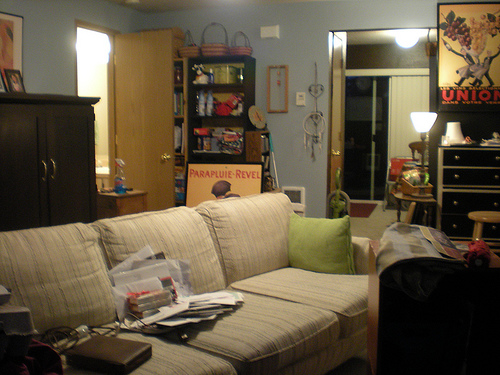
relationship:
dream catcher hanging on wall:
[299, 58, 325, 168] [131, 1, 441, 213]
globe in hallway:
[393, 37, 418, 47] [319, 27, 437, 215]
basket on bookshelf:
[177, 29, 201, 57] [185, 57, 256, 164]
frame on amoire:
[3, 65, 26, 93] [0, 91, 102, 243]